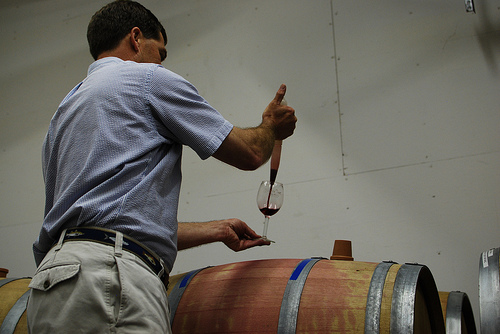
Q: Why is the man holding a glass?
A: To add wine to it.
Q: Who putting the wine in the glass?
A: Man.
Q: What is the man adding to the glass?
A: Wine.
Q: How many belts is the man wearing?
A: 1.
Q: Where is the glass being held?
A: Left hand.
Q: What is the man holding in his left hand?
A: Glass.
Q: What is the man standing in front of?
A: Barrel.